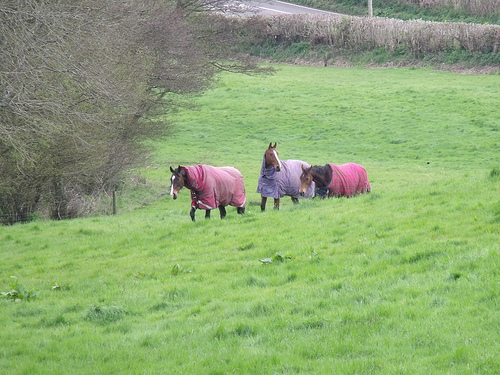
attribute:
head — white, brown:
[168, 167, 187, 200]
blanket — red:
[196, 147, 256, 211]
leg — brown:
[184, 198, 201, 220]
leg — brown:
[202, 202, 213, 222]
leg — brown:
[214, 200, 228, 221]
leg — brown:
[255, 195, 269, 215]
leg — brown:
[271, 194, 283, 214]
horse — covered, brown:
[302, 157, 374, 204]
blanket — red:
[187, 165, 248, 209]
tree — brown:
[102, 6, 234, 138]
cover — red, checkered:
[333, 165, 369, 192]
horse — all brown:
[298, 166, 370, 193]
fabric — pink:
[197, 168, 242, 199]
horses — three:
[157, 151, 382, 212]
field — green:
[27, 55, 497, 370]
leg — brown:
[223, 194, 247, 221]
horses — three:
[154, 142, 370, 189]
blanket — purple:
[257, 157, 317, 199]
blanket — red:
[320, 161, 370, 194]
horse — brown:
[258, 141, 314, 210]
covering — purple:
[262, 160, 312, 200]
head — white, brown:
[170, 164, 183, 199]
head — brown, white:
[261, 139, 283, 173]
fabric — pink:
[311, 158, 371, 201]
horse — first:
[167, 159, 251, 223]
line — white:
[228, 0, 297, 18]